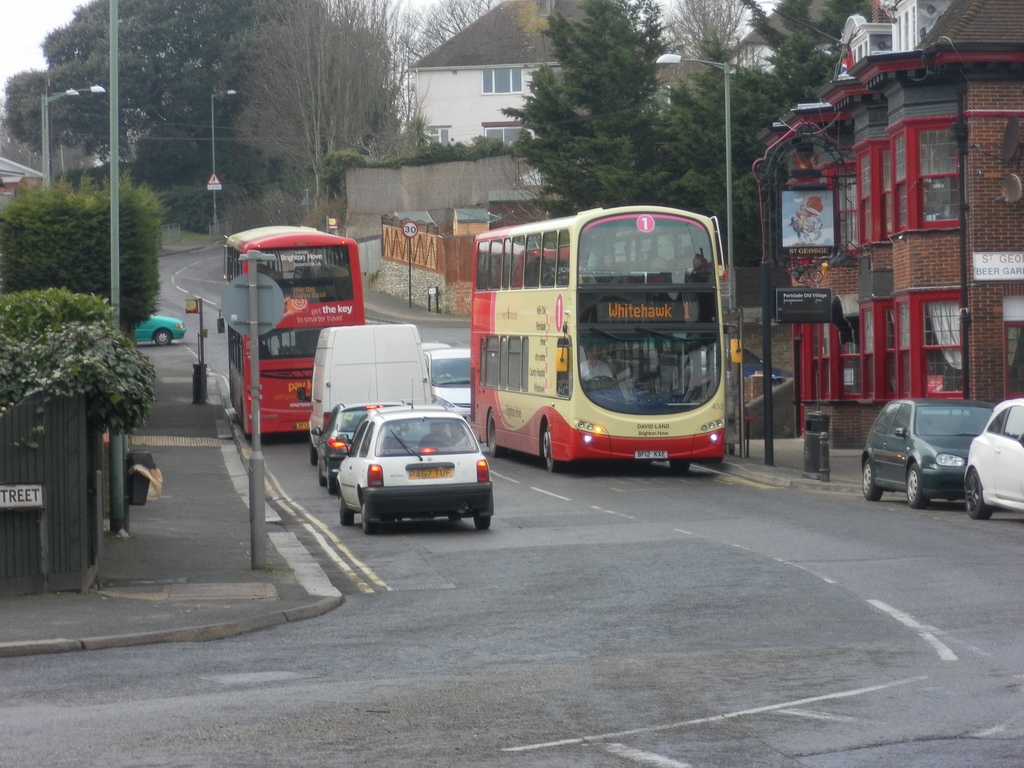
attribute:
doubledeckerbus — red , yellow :
[471, 207, 731, 474]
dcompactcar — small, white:
[330, 412, 495, 531]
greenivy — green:
[4, 276, 151, 429]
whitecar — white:
[332, 410, 492, 537]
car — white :
[964, 394, 1016, 519]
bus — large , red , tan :
[465, 207, 728, 474]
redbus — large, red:
[220, 223, 377, 440]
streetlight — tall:
[103, 2, 122, 354]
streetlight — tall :
[656, 53, 733, 471]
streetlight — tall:
[212, 84, 241, 240]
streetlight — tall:
[40, 84, 104, 198]